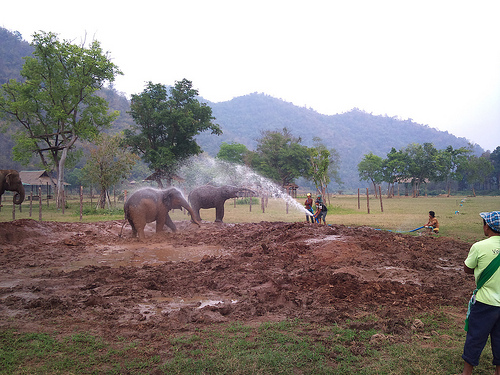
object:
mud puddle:
[128, 287, 246, 317]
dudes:
[313, 200, 328, 227]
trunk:
[239, 187, 256, 194]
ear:
[162, 191, 172, 208]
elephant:
[186, 183, 259, 225]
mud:
[175, 215, 354, 285]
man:
[303, 192, 314, 224]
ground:
[0, 191, 500, 375]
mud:
[17, 214, 457, 316]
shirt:
[463, 235, 500, 308]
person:
[424, 210, 441, 235]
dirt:
[0, 215, 483, 338]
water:
[174, 152, 313, 217]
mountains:
[130, 80, 261, 160]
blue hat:
[477, 209, 499, 233]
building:
[12, 168, 71, 207]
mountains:
[0, 24, 135, 191]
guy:
[457, 208, 500, 375]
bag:
[462, 253, 500, 333]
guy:
[316, 194, 324, 225]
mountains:
[213, 89, 410, 193]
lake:
[51, 242, 233, 272]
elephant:
[119, 183, 201, 242]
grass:
[0, 312, 493, 374]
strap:
[477, 253, 500, 292]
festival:
[110, 158, 334, 241]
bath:
[116, 152, 329, 240]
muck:
[0, 216, 480, 339]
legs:
[155, 206, 168, 234]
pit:
[3, 241, 435, 316]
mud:
[0, 238, 392, 292]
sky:
[0, 0, 500, 152]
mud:
[104, 240, 217, 290]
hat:
[306, 192, 312, 196]